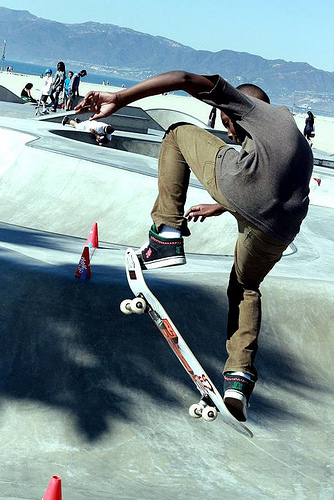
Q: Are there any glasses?
A: No, there are no glasses.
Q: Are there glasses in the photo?
A: No, there are no glasses.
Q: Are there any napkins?
A: No, there are no napkins.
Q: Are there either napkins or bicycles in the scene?
A: No, there are no napkins or bicycles.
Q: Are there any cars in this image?
A: No, there are no cars.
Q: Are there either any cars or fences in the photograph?
A: No, there are no cars or fences.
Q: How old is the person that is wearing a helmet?
A: The person is young.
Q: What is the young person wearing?
A: The person is wearing a helmet.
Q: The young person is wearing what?
A: The person is wearing a helmet.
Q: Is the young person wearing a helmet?
A: Yes, the person is wearing a helmet.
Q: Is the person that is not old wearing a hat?
A: No, the person is wearing a helmet.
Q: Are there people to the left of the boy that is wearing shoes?
A: Yes, there is a person to the left of the boy.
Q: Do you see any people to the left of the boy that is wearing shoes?
A: Yes, there is a person to the left of the boy.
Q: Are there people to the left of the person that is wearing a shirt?
A: Yes, there is a person to the left of the boy.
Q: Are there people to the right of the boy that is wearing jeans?
A: No, the person is to the left of the boy.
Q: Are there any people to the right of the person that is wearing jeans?
A: No, the person is to the left of the boy.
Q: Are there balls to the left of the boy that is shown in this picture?
A: No, there is a person to the left of the boy.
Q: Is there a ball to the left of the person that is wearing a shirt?
A: No, there is a person to the left of the boy.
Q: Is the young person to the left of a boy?
A: Yes, the person is to the left of a boy.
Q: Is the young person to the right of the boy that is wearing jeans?
A: No, the person is to the left of the boy.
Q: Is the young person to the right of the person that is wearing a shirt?
A: No, the person is to the left of the boy.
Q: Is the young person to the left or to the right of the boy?
A: The person is to the left of the boy.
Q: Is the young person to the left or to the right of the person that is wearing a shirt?
A: The person is to the left of the boy.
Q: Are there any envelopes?
A: No, there are no envelopes.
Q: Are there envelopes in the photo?
A: No, there are no envelopes.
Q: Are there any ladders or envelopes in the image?
A: No, there are no envelopes or ladders.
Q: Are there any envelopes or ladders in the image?
A: No, there are no envelopes or ladders.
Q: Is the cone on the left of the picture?
A: Yes, the cone is on the left of the image.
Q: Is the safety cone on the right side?
A: No, the safety cone is on the left of the image.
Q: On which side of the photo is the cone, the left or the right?
A: The cone is on the left of the image.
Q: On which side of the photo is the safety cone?
A: The safety cone is on the left of the image.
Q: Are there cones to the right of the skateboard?
A: No, the cone is to the left of the skateboard.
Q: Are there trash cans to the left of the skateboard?
A: No, there is a cone to the left of the skateboard.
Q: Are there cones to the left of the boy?
A: Yes, there is a cone to the left of the boy.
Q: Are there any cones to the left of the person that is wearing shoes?
A: Yes, there is a cone to the left of the boy.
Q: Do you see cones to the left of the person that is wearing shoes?
A: Yes, there is a cone to the left of the boy.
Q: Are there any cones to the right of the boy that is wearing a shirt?
A: No, the cone is to the left of the boy.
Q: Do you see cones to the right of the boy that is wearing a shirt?
A: No, the cone is to the left of the boy.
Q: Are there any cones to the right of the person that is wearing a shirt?
A: No, the cone is to the left of the boy.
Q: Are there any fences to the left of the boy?
A: No, there is a cone to the left of the boy.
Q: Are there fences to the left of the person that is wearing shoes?
A: No, there is a cone to the left of the boy.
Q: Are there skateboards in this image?
A: Yes, there is a skateboard.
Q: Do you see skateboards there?
A: Yes, there is a skateboard.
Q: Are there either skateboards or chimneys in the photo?
A: Yes, there is a skateboard.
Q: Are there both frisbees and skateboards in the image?
A: No, there is a skateboard but no frisbees.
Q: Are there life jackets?
A: No, there are no life jackets.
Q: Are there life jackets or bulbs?
A: No, there are no life jackets or bulbs.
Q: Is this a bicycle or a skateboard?
A: This is a skateboard.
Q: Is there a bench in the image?
A: No, there are no benches.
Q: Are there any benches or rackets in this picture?
A: No, there are no benches or rackets.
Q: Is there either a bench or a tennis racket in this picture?
A: No, there are no benches or rackets.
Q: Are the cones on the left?
A: Yes, the cones are on the left of the image.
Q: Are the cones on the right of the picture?
A: No, the cones are on the left of the image.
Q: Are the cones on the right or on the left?
A: The cones are on the left of the image.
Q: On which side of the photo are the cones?
A: The cones are on the left of the image.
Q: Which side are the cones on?
A: The cones are on the left of the image.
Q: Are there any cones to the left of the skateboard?
A: Yes, there are cones to the left of the skateboard.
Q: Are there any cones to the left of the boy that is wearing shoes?
A: Yes, there are cones to the left of the boy.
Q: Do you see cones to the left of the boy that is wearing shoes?
A: Yes, there are cones to the left of the boy.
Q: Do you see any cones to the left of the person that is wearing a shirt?
A: Yes, there are cones to the left of the boy.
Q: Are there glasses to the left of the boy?
A: No, there are cones to the left of the boy.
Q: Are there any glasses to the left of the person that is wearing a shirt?
A: No, there are cones to the left of the boy.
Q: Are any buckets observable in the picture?
A: No, there are no buckets.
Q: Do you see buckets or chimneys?
A: No, there are no buckets or chimneys.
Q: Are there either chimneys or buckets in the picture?
A: No, there are no buckets or chimneys.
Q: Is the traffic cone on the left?
A: Yes, the traffic cone is on the left of the image.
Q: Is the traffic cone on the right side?
A: No, the traffic cone is on the left of the image.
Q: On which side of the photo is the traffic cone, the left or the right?
A: The traffic cone is on the left of the image.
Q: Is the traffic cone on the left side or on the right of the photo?
A: The traffic cone is on the left of the image.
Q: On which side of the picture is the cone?
A: The cone is on the left of the image.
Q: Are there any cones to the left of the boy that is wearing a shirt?
A: Yes, there is a cone to the left of the boy.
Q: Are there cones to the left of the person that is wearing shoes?
A: Yes, there is a cone to the left of the boy.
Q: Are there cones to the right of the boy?
A: No, the cone is to the left of the boy.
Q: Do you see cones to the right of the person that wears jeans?
A: No, the cone is to the left of the boy.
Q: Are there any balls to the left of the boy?
A: No, there is a cone to the left of the boy.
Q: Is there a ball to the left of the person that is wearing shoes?
A: No, there is a cone to the left of the boy.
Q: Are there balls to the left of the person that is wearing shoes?
A: No, there is a cone to the left of the boy.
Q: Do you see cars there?
A: No, there are no cars.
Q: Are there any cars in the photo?
A: No, there are no cars.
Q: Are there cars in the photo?
A: No, there are no cars.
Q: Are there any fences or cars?
A: No, there are no cars or fences.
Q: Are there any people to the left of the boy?
A: Yes, there is a person to the left of the boy.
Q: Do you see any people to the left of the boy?
A: Yes, there is a person to the left of the boy.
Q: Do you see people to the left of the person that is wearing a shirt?
A: Yes, there is a person to the left of the boy.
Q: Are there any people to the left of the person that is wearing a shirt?
A: Yes, there is a person to the left of the boy.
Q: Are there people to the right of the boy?
A: No, the person is to the left of the boy.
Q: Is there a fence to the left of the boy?
A: No, there is a person to the left of the boy.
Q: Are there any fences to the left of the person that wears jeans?
A: No, there is a person to the left of the boy.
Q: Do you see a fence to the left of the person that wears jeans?
A: No, there is a person to the left of the boy.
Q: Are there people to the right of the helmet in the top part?
A: Yes, there is a person to the right of the helmet.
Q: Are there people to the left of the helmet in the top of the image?
A: No, the person is to the right of the helmet.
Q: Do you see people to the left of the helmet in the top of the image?
A: No, the person is to the right of the helmet.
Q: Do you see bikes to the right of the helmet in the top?
A: No, there is a person to the right of the helmet.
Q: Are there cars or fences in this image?
A: No, there are no fences or cars.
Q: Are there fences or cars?
A: No, there are no fences or cars.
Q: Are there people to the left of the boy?
A: Yes, there is a person to the left of the boy.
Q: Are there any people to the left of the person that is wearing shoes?
A: Yes, there is a person to the left of the boy.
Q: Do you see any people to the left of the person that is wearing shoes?
A: Yes, there is a person to the left of the boy.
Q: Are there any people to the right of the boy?
A: No, the person is to the left of the boy.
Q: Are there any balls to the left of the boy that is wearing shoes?
A: No, there is a person to the left of the boy.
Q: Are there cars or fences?
A: No, there are no cars or fences.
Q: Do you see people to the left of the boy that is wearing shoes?
A: Yes, there is a person to the left of the boy.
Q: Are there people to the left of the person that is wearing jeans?
A: Yes, there is a person to the left of the boy.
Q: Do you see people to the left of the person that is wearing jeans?
A: Yes, there is a person to the left of the boy.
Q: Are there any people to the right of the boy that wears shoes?
A: No, the person is to the left of the boy.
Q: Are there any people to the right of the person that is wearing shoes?
A: No, the person is to the left of the boy.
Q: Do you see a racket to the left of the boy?
A: No, there is a person to the left of the boy.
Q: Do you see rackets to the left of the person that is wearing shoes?
A: No, there is a person to the left of the boy.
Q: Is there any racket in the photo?
A: No, there are no rackets.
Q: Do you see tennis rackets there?
A: No, there are no tennis rackets.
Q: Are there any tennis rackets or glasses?
A: No, there are no tennis rackets or glasses.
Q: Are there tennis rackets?
A: No, there are no tennis rackets.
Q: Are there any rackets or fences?
A: No, there are no rackets or fences.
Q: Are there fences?
A: No, there are no fences.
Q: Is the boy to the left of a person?
A: No, the boy is to the right of a person.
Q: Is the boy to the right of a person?
A: Yes, the boy is to the right of a person.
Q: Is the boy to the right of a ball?
A: No, the boy is to the right of a person.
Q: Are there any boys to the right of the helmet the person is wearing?
A: Yes, there is a boy to the right of the helmet.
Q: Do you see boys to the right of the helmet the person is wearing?
A: Yes, there is a boy to the right of the helmet.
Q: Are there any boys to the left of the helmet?
A: No, the boy is to the right of the helmet.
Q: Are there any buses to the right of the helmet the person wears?
A: No, there is a boy to the right of the helmet.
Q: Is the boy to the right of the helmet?
A: Yes, the boy is to the right of the helmet.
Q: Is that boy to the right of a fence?
A: No, the boy is to the right of the helmet.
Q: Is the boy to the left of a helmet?
A: No, the boy is to the right of a helmet.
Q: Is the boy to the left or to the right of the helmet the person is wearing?
A: The boy is to the right of the helmet.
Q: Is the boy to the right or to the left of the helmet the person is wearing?
A: The boy is to the right of the helmet.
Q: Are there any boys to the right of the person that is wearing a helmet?
A: Yes, there is a boy to the right of the person.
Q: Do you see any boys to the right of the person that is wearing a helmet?
A: Yes, there is a boy to the right of the person.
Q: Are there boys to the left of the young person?
A: No, the boy is to the right of the person.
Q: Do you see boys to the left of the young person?
A: No, the boy is to the right of the person.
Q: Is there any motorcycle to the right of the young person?
A: No, there is a boy to the right of the person.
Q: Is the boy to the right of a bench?
A: No, the boy is to the right of a person.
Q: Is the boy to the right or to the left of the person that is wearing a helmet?
A: The boy is to the right of the person.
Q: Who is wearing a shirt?
A: The boy is wearing a shirt.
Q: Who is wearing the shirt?
A: The boy is wearing a shirt.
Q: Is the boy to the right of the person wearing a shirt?
A: Yes, the boy is wearing a shirt.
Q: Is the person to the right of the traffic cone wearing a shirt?
A: Yes, the boy is wearing a shirt.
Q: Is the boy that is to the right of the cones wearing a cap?
A: No, the boy is wearing a shirt.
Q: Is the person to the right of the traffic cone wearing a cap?
A: No, the boy is wearing a shirt.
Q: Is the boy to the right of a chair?
A: No, the boy is to the right of a person.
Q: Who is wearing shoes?
A: The boy is wearing shoes.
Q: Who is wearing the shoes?
A: The boy is wearing shoes.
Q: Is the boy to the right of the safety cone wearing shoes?
A: Yes, the boy is wearing shoes.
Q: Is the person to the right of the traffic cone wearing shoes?
A: Yes, the boy is wearing shoes.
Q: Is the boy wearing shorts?
A: No, the boy is wearing shoes.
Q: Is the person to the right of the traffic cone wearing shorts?
A: No, the boy is wearing shoes.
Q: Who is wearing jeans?
A: The boy is wearing jeans.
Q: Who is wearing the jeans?
A: The boy is wearing jeans.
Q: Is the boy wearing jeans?
A: Yes, the boy is wearing jeans.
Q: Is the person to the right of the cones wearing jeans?
A: Yes, the boy is wearing jeans.